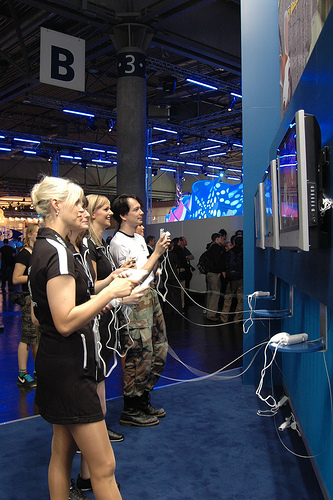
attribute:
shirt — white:
[104, 231, 151, 298]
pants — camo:
[122, 293, 170, 396]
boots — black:
[120, 395, 167, 428]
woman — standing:
[7, 223, 38, 389]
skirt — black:
[37, 332, 106, 425]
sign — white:
[37, 24, 87, 92]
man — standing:
[106, 194, 168, 429]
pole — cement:
[111, 19, 150, 234]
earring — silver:
[56, 209, 60, 218]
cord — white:
[150, 286, 288, 333]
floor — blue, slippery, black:
[2, 293, 250, 427]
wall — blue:
[255, 10, 333, 500]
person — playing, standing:
[87, 194, 114, 283]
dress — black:
[28, 227, 105, 426]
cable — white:
[162, 247, 285, 314]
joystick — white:
[165, 229, 172, 239]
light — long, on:
[185, 76, 220, 92]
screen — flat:
[275, 110, 331, 255]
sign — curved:
[164, 179, 247, 222]